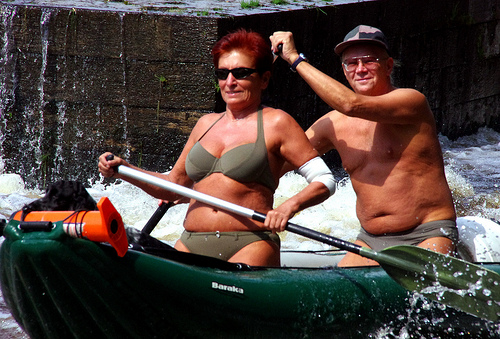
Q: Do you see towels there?
A: No, there are no towels.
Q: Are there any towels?
A: No, there are no towels.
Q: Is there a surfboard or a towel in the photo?
A: No, there are no towels or surfboards.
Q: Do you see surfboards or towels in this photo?
A: No, there are no towels or surfboards.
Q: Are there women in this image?
A: Yes, there is a woman.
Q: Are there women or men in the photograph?
A: Yes, there is a woman.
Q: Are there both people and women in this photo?
A: Yes, there are both a woman and people.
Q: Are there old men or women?
A: Yes, there is an old woman.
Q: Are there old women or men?
A: Yes, there is an old woman.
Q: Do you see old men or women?
A: Yes, there is an old woman.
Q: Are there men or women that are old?
A: Yes, the woman is old.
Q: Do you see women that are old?
A: Yes, there is an old woman.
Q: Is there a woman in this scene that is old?
A: Yes, there is a woman that is old.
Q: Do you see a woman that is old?
A: Yes, there is a woman that is old.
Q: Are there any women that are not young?
A: Yes, there is a old woman.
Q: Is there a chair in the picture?
A: No, there are no chairs.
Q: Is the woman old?
A: Yes, the woman is old.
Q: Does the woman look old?
A: Yes, the woman is old.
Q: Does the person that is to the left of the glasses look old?
A: Yes, the woman is old.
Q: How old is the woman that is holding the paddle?
A: The woman is old.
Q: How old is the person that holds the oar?
A: The woman is old.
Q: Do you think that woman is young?
A: No, the woman is old.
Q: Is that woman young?
A: No, the woman is old.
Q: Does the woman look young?
A: No, the woman is old.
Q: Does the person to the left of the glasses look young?
A: No, the woman is old.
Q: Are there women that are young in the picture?
A: No, there is a woman but she is old.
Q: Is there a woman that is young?
A: No, there is a woman but she is old.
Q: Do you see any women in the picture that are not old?
A: No, there is a woman but she is old.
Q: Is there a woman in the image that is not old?
A: No, there is a woman but she is old.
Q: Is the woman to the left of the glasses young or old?
A: The woman is old.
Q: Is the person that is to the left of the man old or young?
A: The woman is old.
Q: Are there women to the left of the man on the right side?
A: Yes, there is a woman to the left of the man.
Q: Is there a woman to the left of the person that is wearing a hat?
A: Yes, there is a woman to the left of the man.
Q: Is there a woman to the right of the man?
A: No, the woman is to the left of the man.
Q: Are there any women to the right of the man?
A: No, the woman is to the left of the man.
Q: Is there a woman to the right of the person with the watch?
A: No, the woman is to the left of the man.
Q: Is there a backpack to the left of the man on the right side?
A: No, there is a woman to the left of the man.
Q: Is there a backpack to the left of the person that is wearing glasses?
A: No, there is a woman to the left of the man.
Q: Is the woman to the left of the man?
A: Yes, the woman is to the left of the man.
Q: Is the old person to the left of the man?
A: Yes, the woman is to the left of the man.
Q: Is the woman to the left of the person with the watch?
A: Yes, the woman is to the left of the man.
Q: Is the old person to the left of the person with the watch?
A: Yes, the woman is to the left of the man.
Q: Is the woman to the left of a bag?
A: No, the woman is to the left of the man.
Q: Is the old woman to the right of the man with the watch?
A: No, the woman is to the left of the man.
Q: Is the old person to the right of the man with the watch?
A: No, the woman is to the left of the man.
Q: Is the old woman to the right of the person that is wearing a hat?
A: No, the woman is to the left of the man.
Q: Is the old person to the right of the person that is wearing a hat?
A: No, the woman is to the left of the man.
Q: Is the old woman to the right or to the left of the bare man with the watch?
A: The woman is to the left of the man.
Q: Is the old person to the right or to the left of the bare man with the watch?
A: The woman is to the left of the man.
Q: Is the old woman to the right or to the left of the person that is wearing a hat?
A: The woman is to the left of the man.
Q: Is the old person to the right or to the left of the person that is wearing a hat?
A: The woman is to the left of the man.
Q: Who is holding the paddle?
A: The woman is holding the paddle.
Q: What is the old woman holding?
A: The woman is holding the paddle.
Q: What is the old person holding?
A: The woman is holding the paddle.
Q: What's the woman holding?
A: The woman is holding the paddle.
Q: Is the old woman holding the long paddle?
A: Yes, the woman is holding the oar.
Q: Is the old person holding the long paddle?
A: Yes, the woman is holding the oar.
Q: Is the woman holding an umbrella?
A: No, the woman is holding the oar.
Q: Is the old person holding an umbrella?
A: No, the woman is holding the oar.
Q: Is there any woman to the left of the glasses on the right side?
A: Yes, there is a woman to the left of the glasses.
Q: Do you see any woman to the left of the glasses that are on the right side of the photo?
A: Yes, there is a woman to the left of the glasses.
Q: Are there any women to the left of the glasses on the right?
A: Yes, there is a woman to the left of the glasses.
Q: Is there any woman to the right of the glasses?
A: No, the woman is to the left of the glasses.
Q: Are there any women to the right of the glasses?
A: No, the woman is to the left of the glasses.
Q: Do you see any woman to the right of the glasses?
A: No, the woman is to the left of the glasses.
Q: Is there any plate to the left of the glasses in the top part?
A: No, there is a woman to the left of the glasses.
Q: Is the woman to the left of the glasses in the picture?
A: Yes, the woman is to the left of the glasses.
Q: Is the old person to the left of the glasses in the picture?
A: Yes, the woman is to the left of the glasses.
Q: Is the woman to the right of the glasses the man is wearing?
A: No, the woman is to the left of the glasses.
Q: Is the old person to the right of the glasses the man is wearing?
A: No, the woman is to the left of the glasses.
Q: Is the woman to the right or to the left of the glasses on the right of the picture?
A: The woman is to the left of the glasses.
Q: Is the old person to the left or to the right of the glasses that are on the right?
A: The woman is to the left of the glasses.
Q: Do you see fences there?
A: No, there are no fences.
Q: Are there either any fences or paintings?
A: No, there are no fences or paintings.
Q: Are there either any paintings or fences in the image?
A: No, there are no fences or paintings.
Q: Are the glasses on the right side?
A: Yes, the glasses are on the right of the image.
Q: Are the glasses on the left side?
A: No, the glasses are on the right of the image.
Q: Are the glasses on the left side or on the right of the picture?
A: The glasses are on the right of the image.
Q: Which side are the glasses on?
A: The glasses are on the right of the image.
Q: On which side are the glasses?
A: The glasses are on the right of the image.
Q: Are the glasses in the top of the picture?
A: Yes, the glasses are in the top of the image.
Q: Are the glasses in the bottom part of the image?
A: No, the glasses are in the top of the image.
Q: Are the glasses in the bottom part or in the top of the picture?
A: The glasses are in the top of the image.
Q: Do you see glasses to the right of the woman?
A: Yes, there are glasses to the right of the woman.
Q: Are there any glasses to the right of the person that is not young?
A: Yes, there are glasses to the right of the woman.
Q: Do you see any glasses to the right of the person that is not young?
A: Yes, there are glasses to the right of the woman.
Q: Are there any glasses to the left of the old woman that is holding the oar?
A: No, the glasses are to the right of the woman.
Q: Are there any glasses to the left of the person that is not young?
A: No, the glasses are to the right of the woman.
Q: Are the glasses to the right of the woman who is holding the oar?
A: Yes, the glasses are to the right of the woman.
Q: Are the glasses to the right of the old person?
A: Yes, the glasses are to the right of the woman.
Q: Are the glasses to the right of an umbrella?
A: No, the glasses are to the right of the woman.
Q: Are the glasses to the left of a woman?
A: No, the glasses are to the right of a woman.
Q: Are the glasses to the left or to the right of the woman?
A: The glasses are to the right of the woman.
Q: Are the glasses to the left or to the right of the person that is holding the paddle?
A: The glasses are to the right of the woman.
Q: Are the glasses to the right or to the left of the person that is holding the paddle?
A: The glasses are to the right of the woman.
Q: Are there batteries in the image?
A: No, there are no batteries.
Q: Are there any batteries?
A: No, there are no batteries.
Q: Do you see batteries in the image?
A: No, there are no batteries.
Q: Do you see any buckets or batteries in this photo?
A: No, there are no batteries or buckets.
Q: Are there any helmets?
A: No, there are no helmets.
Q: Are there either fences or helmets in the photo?
A: No, there are no helmets or fences.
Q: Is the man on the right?
A: Yes, the man is on the right of the image.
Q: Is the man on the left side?
A: No, the man is on the right of the image.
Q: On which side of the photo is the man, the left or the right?
A: The man is on the right of the image.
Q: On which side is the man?
A: The man is on the right of the image.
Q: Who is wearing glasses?
A: The man is wearing glasses.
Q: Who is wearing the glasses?
A: The man is wearing glasses.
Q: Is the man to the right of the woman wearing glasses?
A: Yes, the man is wearing glasses.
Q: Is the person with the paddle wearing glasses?
A: Yes, the man is wearing glasses.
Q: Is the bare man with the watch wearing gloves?
A: No, the man is wearing glasses.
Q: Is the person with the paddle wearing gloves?
A: No, the man is wearing glasses.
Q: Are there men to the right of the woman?
A: Yes, there is a man to the right of the woman.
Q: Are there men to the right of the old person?
A: Yes, there is a man to the right of the woman.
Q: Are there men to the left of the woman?
A: No, the man is to the right of the woman.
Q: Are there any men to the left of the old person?
A: No, the man is to the right of the woman.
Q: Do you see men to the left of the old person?
A: No, the man is to the right of the woman.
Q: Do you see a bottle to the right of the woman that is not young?
A: No, there is a man to the right of the woman.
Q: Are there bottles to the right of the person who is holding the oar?
A: No, there is a man to the right of the woman.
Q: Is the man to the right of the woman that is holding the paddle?
A: Yes, the man is to the right of the woman.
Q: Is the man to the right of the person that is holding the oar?
A: Yes, the man is to the right of the woman.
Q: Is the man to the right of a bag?
A: No, the man is to the right of the woman.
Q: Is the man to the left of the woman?
A: No, the man is to the right of the woman.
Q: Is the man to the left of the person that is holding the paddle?
A: No, the man is to the right of the woman.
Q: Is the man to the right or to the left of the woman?
A: The man is to the right of the woman.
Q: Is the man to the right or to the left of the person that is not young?
A: The man is to the right of the woman.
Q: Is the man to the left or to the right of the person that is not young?
A: The man is to the right of the woman.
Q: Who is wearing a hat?
A: The man is wearing a hat.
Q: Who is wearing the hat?
A: The man is wearing a hat.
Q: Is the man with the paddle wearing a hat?
A: Yes, the man is wearing a hat.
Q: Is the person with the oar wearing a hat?
A: Yes, the man is wearing a hat.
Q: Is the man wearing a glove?
A: No, the man is wearing a hat.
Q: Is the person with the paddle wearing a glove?
A: No, the man is wearing a hat.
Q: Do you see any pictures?
A: No, there are no pictures.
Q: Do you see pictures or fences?
A: No, there are no pictures or fences.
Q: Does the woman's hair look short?
A: Yes, the hair is short.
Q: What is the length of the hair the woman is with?
A: The hair is short.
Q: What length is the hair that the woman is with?
A: The hair is short.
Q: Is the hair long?
A: No, the hair is short.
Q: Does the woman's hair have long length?
A: No, the hair is short.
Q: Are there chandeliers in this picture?
A: No, there are no chandeliers.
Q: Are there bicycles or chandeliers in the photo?
A: No, there are no chandeliers or bicycles.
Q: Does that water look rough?
A: Yes, the water is rough.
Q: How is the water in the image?
A: The water is rough.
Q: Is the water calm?
A: No, the water is rough.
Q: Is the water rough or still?
A: The water is rough.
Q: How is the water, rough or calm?
A: The water is rough.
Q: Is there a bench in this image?
A: No, there are no benches.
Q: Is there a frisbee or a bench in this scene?
A: No, there are no benches or frisbees.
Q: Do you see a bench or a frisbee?
A: No, there are no benches or frisbees.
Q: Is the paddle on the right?
A: Yes, the paddle is on the right of the image.